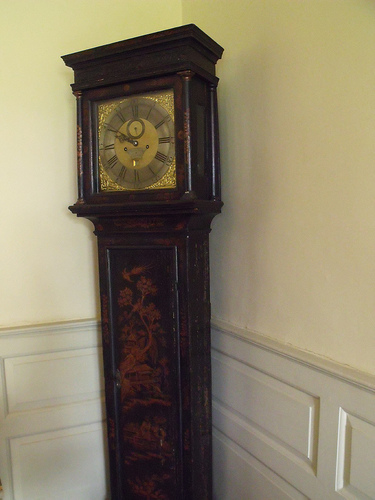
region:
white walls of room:
[2, 2, 372, 495]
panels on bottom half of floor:
[216, 350, 369, 498]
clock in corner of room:
[59, 23, 222, 497]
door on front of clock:
[113, 248, 181, 497]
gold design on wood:
[119, 265, 172, 496]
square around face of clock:
[95, 87, 177, 191]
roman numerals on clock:
[102, 102, 168, 184]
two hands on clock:
[110, 125, 137, 146]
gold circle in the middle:
[113, 116, 157, 169]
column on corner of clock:
[180, 72, 197, 197]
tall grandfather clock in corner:
[58, 34, 237, 490]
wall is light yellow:
[244, 133, 337, 300]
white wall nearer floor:
[200, 348, 374, 498]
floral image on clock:
[98, 241, 195, 498]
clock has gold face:
[78, 82, 168, 184]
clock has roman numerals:
[106, 98, 163, 185]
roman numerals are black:
[102, 110, 176, 183]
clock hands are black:
[90, 98, 175, 183]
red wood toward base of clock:
[92, 256, 223, 492]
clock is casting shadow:
[218, 70, 290, 305]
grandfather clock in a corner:
[61, 19, 229, 489]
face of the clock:
[71, 86, 192, 195]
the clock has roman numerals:
[87, 84, 198, 198]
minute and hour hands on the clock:
[109, 122, 146, 152]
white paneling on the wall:
[0, 302, 370, 492]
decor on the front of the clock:
[112, 222, 180, 493]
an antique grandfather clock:
[65, 15, 230, 497]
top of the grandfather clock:
[60, 24, 226, 227]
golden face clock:
[81, 84, 182, 189]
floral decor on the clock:
[101, 257, 179, 489]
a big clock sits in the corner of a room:
[53, 28, 218, 499]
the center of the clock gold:
[74, 94, 178, 183]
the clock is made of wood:
[53, 18, 208, 491]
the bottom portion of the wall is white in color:
[5, 338, 371, 498]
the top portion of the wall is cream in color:
[9, 11, 370, 354]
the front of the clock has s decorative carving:
[106, 258, 181, 498]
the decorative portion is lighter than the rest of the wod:
[107, 244, 170, 498]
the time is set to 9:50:
[96, 103, 175, 188]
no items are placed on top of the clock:
[62, 3, 232, 53]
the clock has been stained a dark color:
[63, 24, 229, 491]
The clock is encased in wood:
[80, 59, 214, 205]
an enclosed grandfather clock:
[91, 118, 234, 497]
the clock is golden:
[103, 98, 174, 188]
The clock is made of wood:
[111, 263, 199, 471]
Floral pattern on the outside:
[117, 269, 169, 487]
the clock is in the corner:
[46, 37, 229, 343]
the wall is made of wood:
[214, 333, 373, 497]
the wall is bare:
[232, 21, 370, 483]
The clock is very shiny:
[90, 82, 177, 203]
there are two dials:
[99, 104, 160, 181]